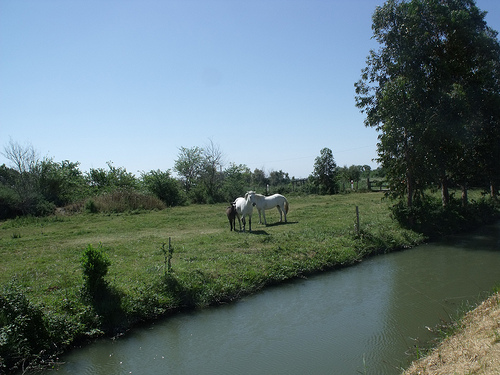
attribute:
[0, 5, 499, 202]
sky — blue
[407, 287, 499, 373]
grass — dead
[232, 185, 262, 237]
horse — white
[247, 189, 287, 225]
horse — white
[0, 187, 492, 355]
grass — green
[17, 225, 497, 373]
water — calm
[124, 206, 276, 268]
grass — short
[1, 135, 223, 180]
cloud — white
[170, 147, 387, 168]
cloud — white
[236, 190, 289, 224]
horse — white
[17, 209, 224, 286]
field — green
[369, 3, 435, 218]
tree — tall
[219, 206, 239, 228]
baby horse — brown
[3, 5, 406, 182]
sky — clear, blue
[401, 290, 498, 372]
grass — dried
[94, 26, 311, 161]
skies — blue, clear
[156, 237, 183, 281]
plants — green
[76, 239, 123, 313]
plants — green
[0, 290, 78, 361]
plants — green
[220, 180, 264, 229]
horse — young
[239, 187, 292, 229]
horse — white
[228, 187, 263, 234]
horse — white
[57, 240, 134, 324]
bush — tall